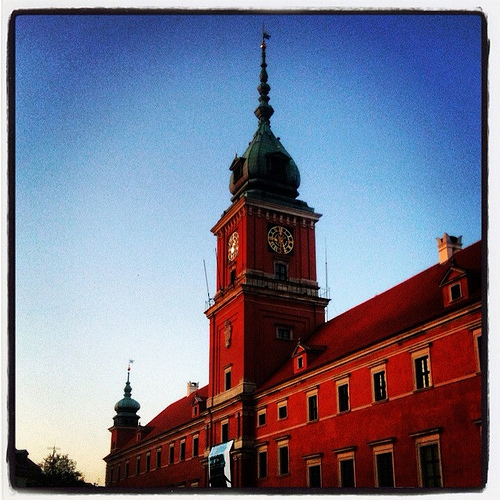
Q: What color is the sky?
A: Blue.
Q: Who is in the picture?
A: No one.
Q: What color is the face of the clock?
A: Black.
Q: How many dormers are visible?
A: Four.